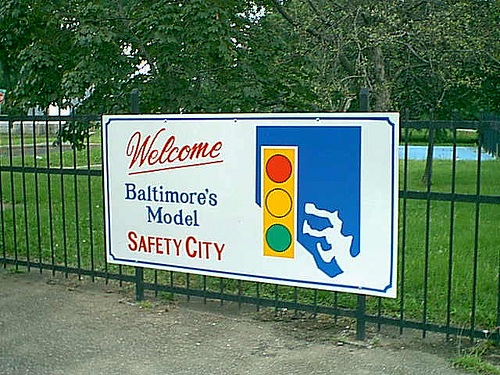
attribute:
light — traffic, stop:
[256, 137, 311, 259]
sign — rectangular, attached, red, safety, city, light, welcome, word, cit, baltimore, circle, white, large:
[86, 78, 405, 283]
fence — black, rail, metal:
[19, 55, 470, 329]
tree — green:
[136, 20, 364, 103]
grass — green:
[87, 202, 99, 227]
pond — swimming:
[380, 130, 486, 170]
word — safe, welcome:
[108, 127, 264, 285]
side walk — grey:
[73, 301, 159, 372]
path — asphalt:
[80, 310, 118, 342]